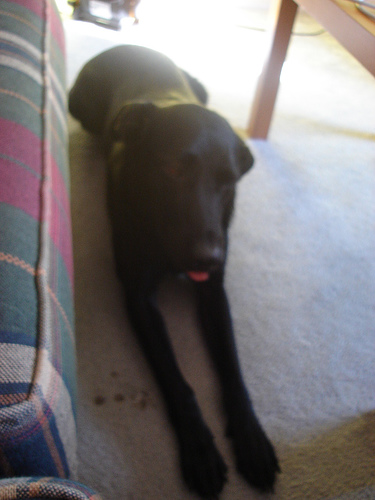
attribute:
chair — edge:
[246, 0, 372, 190]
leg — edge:
[188, 308, 304, 489]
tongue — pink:
[190, 270, 210, 281]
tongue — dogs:
[184, 264, 217, 284]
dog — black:
[69, 43, 280, 495]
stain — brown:
[91, 392, 106, 405]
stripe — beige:
[2, 343, 77, 478]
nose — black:
[186, 237, 229, 267]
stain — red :
[92, 371, 124, 397]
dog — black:
[84, 41, 262, 396]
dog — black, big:
[64, 21, 303, 495]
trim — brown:
[271, 406, 360, 494]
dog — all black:
[70, 45, 286, 438]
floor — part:
[55, 1, 373, 496]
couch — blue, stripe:
[0, 0, 110, 499]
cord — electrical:
[212, 22, 311, 135]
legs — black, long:
[138, 289, 286, 490]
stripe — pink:
[9, 132, 57, 210]